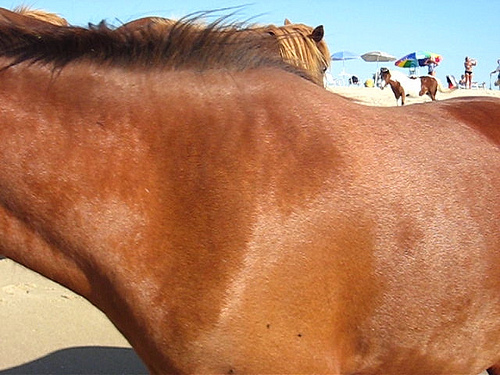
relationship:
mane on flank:
[0, 3, 322, 96] [0, 8, 499, 374]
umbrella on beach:
[396, 52, 443, 70] [1, 0, 499, 375]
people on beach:
[425, 55, 500, 90] [1, 0, 499, 375]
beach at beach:
[1, 83, 499, 375] [1, 0, 499, 375]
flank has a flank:
[0, 8, 499, 374] [482, 348, 498, 374]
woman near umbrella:
[463, 56, 476, 88] [396, 52, 443, 70]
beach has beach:
[1, 0, 499, 375] [1, 83, 499, 375]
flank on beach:
[0, 8, 499, 374] [1, 83, 499, 375]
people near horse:
[425, 55, 500, 90] [379, 72, 438, 106]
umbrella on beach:
[396, 52, 443, 70] [1, 83, 499, 375]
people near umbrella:
[425, 55, 500, 90] [396, 52, 443, 70]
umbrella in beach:
[396, 52, 443, 70] [1, 83, 499, 375]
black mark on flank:
[297, 332, 302, 338] [0, 8, 499, 374]